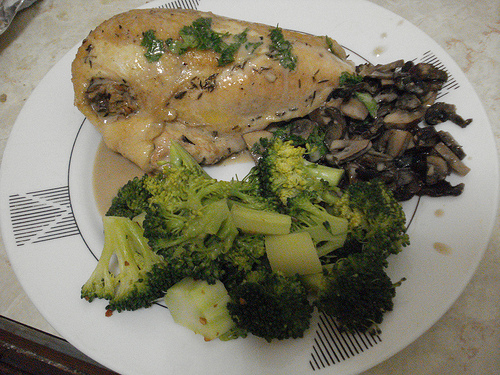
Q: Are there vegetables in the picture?
A: Yes, there are vegetables.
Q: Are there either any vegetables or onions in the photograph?
A: Yes, there are vegetables.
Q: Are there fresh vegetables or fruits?
A: Yes, there are fresh vegetables.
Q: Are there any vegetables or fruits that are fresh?
A: Yes, the vegetables are fresh.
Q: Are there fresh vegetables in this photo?
A: Yes, there are fresh vegetables.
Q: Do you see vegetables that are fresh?
A: Yes, there are vegetables that are fresh.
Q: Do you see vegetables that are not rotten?
A: Yes, there are fresh vegetables.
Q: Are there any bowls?
A: No, there are no bowls.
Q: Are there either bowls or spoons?
A: No, there are no bowls or spoons.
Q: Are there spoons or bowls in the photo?
A: No, there are no bowls or spoons.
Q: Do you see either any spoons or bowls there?
A: No, there are no bowls or spoons.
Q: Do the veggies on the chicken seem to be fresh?
A: Yes, the vegetables are fresh.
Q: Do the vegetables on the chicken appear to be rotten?
A: No, the veggies are fresh.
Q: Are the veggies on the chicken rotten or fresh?
A: The veggies are fresh.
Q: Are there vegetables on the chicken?
A: Yes, there are vegetables on the chicken.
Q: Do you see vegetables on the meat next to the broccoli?
A: Yes, there are vegetables on the chicken.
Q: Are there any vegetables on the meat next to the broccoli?
A: Yes, there are vegetables on the chicken.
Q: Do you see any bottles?
A: No, there are no bottles.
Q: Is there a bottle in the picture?
A: No, there are no bottles.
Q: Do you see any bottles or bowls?
A: No, there are no bottles or bowls.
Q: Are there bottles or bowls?
A: No, there are no bottles or bowls.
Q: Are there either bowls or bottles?
A: No, there are no bottles or bowls.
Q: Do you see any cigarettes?
A: No, there are no cigarettes.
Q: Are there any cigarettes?
A: No, there are no cigarettes.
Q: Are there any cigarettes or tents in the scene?
A: No, there are no cigarettes or tents.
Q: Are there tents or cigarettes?
A: No, there are no cigarettes or tents.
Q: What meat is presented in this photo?
A: The meat is chicken.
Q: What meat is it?
A: The meat is chicken.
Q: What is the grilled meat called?
A: The meat is chicken.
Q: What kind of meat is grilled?
A: The meat is chicken.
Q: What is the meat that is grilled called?
A: The meat is chicken.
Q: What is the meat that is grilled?
A: The meat is chicken.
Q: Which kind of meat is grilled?
A: The meat is chicken.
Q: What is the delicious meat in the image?
A: The meat is chicken.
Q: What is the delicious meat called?
A: The meat is chicken.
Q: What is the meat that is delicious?
A: The meat is chicken.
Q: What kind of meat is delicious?
A: The meat is chicken.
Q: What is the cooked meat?
A: The meat is chicken.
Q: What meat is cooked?
A: The meat is chicken.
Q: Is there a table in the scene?
A: Yes, there is a table.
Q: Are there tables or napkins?
A: Yes, there is a table.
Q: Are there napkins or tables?
A: Yes, there is a table.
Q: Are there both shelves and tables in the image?
A: No, there is a table but no shelves.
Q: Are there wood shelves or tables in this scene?
A: Yes, there is a wood table.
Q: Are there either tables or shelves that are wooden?
A: Yes, the table is wooden.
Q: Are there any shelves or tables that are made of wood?
A: Yes, the table is made of wood.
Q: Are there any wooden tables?
A: Yes, there is a wood table.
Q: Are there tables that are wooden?
A: Yes, there is a table that is wooden.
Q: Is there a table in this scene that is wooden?
A: Yes, there is a table that is wooden.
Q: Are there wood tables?
A: Yes, there is a table that is made of wood.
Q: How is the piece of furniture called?
A: The piece of furniture is a table.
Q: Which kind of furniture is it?
A: The piece of furniture is a table.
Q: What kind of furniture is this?
A: This is a table.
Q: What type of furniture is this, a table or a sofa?
A: This is a table.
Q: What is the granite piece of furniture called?
A: The piece of furniture is a table.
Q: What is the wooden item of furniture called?
A: The piece of furniture is a table.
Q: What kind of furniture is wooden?
A: The furniture is a table.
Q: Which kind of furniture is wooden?
A: The furniture is a table.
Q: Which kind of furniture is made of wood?
A: The furniture is a table.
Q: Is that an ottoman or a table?
A: That is a table.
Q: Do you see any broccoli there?
A: Yes, there is broccoli.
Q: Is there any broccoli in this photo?
A: Yes, there is broccoli.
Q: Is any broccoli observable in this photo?
A: Yes, there is broccoli.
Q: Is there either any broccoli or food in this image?
A: Yes, there is broccoli.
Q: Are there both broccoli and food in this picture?
A: Yes, there are both broccoli and food.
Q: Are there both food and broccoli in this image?
A: Yes, there are both broccoli and food.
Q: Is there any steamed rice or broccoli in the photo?
A: Yes, there is steamed broccoli.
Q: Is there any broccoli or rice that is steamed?
A: Yes, the broccoli is steamed.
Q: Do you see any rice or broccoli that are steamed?
A: Yes, the broccoli is steamed.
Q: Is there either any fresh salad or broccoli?
A: Yes, there is fresh broccoli.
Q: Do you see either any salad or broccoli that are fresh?
A: Yes, the broccoli is fresh.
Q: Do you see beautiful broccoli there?
A: Yes, there is beautiful broccoli.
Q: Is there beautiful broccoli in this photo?
A: Yes, there is beautiful broccoli.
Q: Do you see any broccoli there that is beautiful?
A: Yes, there is broccoli that is beautiful.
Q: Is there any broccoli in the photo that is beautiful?
A: Yes, there is broccoli that is beautiful.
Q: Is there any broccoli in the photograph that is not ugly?
A: Yes, there is beautiful broccoli.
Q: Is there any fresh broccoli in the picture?
A: Yes, there is fresh broccoli.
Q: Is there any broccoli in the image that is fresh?
A: Yes, there is broccoli that is fresh.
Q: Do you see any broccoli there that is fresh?
A: Yes, there is broccoli that is fresh.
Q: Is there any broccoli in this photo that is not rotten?
A: Yes, there is fresh broccoli.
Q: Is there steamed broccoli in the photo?
A: Yes, there is steamed broccoli.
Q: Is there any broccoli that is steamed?
A: Yes, there is broccoli that is steamed.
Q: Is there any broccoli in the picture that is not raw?
A: Yes, there is steamed broccoli.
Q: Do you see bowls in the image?
A: No, there are no bowls.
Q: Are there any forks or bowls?
A: No, there are no bowls or forks.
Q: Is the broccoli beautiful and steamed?
A: Yes, the broccoli is beautiful and steamed.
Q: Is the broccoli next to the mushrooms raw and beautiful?
A: No, the broccoli is beautiful but steamed.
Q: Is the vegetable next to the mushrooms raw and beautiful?
A: No, the broccoli is beautiful but steamed.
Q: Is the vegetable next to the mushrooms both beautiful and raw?
A: No, the broccoli is beautiful but steamed.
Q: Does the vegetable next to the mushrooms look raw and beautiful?
A: No, the broccoli is beautiful but steamed.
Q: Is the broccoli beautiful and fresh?
A: Yes, the broccoli is beautiful and fresh.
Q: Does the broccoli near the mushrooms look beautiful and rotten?
A: No, the broccoli is beautiful but fresh.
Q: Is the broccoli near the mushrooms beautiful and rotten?
A: No, the broccoli is beautiful but fresh.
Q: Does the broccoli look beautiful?
A: Yes, the broccoli is beautiful.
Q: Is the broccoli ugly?
A: No, the broccoli is beautiful.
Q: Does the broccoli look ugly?
A: No, the broccoli is beautiful.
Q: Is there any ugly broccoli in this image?
A: No, there is broccoli but it is beautiful.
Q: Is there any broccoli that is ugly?
A: No, there is broccoli but it is beautiful.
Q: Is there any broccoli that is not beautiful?
A: No, there is broccoli but it is beautiful.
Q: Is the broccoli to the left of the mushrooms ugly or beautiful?
A: The broccoli is beautiful.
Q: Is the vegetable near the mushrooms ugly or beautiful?
A: The broccoli is beautiful.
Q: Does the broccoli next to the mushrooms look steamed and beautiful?
A: Yes, the broccoli is steamed and beautiful.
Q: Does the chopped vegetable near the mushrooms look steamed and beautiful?
A: Yes, the broccoli is steamed and beautiful.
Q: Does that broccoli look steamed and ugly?
A: No, the broccoli is steamed but beautiful.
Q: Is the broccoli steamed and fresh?
A: Yes, the broccoli is steamed and fresh.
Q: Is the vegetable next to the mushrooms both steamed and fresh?
A: Yes, the broccoli is steamed and fresh.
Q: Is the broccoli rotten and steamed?
A: No, the broccoli is steamed but fresh.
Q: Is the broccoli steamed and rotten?
A: No, the broccoli is steamed but fresh.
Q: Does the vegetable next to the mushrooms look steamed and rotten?
A: No, the broccoli is steamed but fresh.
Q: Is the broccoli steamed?
A: Yes, the broccoli is steamed.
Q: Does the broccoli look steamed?
A: Yes, the broccoli is steamed.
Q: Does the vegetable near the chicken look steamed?
A: Yes, the broccoli is steamed.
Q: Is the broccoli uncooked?
A: No, the broccoli is steamed.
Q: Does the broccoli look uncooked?
A: No, the broccoli is steamed.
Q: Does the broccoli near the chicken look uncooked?
A: No, the broccoli is steamed.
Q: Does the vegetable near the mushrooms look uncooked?
A: No, the broccoli is steamed.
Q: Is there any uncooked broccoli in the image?
A: No, there is broccoli but it is steamed.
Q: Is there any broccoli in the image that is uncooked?
A: No, there is broccoli but it is steamed.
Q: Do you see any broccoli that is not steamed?
A: No, there is broccoli but it is steamed.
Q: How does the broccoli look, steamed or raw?
A: The broccoli is steamed.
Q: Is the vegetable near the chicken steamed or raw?
A: The broccoli is steamed.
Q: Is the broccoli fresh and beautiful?
A: Yes, the broccoli is fresh and beautiful.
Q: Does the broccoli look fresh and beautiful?
A: Yes, the broccoli is fresh and beautiful.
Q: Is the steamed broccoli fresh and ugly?
A: No, the broccoli is fresh but beautiful.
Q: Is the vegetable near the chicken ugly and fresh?
A: No, the broccoli is fresh but beautiful.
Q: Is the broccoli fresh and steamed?
A: Yes, the broccoli is fresh and steamed.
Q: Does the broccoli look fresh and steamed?
A: Yes, the broccoli is fresh and steamed.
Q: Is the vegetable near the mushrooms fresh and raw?
A: No, the broccoli is fresh but steamed.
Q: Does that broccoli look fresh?
A: Yes, the broccoli is fresh.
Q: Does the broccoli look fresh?
A: Yes, the broccoli is fresh.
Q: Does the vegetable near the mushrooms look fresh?
A: Yes, the broccoli is fresh.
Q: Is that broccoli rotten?
A: No, the broccoli is fresh.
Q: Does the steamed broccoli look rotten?
A: No, the broccoli is fresh.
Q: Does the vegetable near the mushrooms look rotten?
A: No, the broccoli is fresh.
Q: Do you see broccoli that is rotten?
A: No, there is broccoli but it is fresh.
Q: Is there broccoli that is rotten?
A: No, there is broccoli but it is fresh.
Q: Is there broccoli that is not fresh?
A: No, there is broccoli but it is fresh.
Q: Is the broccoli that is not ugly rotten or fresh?
A: The broccoli is fresh.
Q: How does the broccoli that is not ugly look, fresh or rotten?
A: The broccoli is fresh.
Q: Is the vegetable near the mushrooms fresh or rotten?
A: The broccoli is fresh.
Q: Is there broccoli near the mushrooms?
A: Yes, there is broccoli near the mushrooms.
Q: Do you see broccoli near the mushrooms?
A: Yes, there is broccoli near the mushrooms.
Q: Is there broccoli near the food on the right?
A: Yes, there is broccoli near the mushrooms.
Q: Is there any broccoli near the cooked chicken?
A: Yes, there is broccoli near the chicken.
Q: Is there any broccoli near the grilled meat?
A: Yes, there is broccoli near the chicken.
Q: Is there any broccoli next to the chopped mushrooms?
A: Yes, there is broccoli next to the mushrooms.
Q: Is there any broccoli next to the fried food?
A: Yes, there is broccoli next to the mushrooms.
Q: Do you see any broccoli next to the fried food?
A: Yes, there is broccoli next to the mushrooms.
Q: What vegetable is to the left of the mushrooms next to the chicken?
A: The vegetable is broccoli.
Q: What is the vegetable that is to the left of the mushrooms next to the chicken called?
A: The vegetable is broccoli.